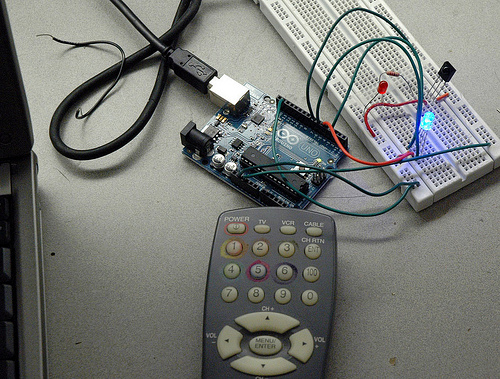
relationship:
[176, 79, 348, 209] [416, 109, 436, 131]
microcontroller to turn on led light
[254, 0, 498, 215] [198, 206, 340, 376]
circuit board by remote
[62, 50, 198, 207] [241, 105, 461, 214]
cord hooked to electronic part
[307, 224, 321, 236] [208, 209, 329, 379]
button on remote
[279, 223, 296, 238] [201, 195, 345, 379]
button on remote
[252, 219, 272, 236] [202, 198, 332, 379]
button on remote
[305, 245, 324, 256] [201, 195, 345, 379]
button on remote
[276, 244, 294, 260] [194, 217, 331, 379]
button on remote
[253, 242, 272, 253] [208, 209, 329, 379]
button on remote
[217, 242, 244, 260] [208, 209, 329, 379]
button on remote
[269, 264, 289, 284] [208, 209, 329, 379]
button on remote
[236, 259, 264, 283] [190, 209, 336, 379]
button on remote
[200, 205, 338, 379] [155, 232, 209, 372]
remote on surface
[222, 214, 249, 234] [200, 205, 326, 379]
power button on remote control